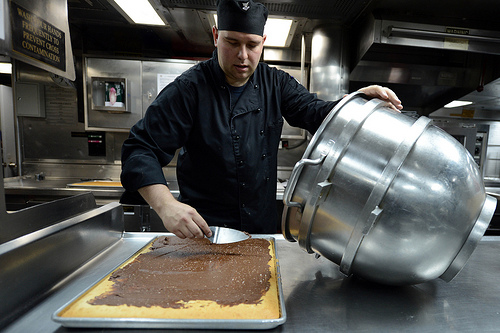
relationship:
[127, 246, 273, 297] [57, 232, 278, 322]
sauce on cake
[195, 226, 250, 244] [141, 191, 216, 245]
spatula in hand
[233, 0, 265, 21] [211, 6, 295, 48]
pin on hat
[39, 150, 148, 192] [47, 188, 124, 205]
dessert on pan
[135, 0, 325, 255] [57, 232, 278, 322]
chef with cake